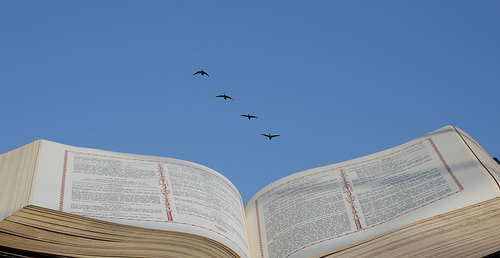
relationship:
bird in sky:
[189, 67, 283, 144] [0, 1, 499, 157]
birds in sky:
[190, 65, 293, 148] [0, 1, 499, 157]